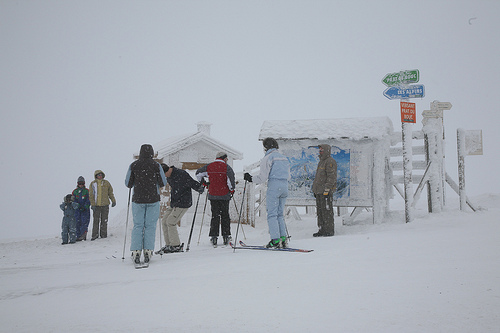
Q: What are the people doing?
A: Skiing.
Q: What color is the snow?
A: White.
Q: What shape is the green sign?
A: An arrow.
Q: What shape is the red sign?
A: Square.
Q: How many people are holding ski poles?
A: Four.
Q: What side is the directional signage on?
A: The right.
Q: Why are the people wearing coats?
A: It is cold and snowing.